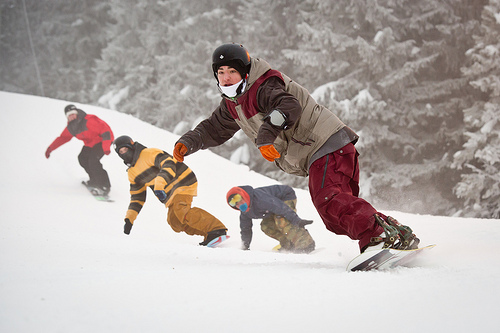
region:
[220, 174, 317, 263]
Man wearing a blue coat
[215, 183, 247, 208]
Goggle on the man's face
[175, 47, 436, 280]
Man wearing maroon pants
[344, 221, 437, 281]
Snowboard on the man's feet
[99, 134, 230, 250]
Man wearing a yellow and black jacket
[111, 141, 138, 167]
Mask covering the man's face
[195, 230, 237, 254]
Snowboard under the man's feet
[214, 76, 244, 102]
Scarf around man's face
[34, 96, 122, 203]
Man wearing a red jacket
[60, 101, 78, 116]
Hat on the man's head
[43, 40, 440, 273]
Four people on snowboards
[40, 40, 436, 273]
Four people snowboarding on a hill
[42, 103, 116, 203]
Snowboarder wearing a red winter coat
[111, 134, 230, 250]
Snowboarder wearing a winter face mask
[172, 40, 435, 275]
Man tilting sideways on a snowboard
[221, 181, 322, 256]
Person touching the snow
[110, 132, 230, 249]
Person wearing a yellow sweater with black stripes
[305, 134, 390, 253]
Burgundy colored snow pants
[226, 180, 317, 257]
Snowboarder with yellow goggles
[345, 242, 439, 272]
White and black snowboard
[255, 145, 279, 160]
an orange snow glove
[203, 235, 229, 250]
white snow board with red design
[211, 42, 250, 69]
a black safety helmet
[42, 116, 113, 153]
a red snow jacket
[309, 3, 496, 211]
snow covered trees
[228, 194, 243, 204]
reflective goggles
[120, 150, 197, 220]
yellow jacket with black stripes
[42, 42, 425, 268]
four snow boarders on the slope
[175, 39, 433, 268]
the man is snow boarding down the hill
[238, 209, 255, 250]
man's arm is on touching the snow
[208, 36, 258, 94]
boy has black cap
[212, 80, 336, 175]
red and grey coat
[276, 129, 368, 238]
boy has red pants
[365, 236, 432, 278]
boy has black shoes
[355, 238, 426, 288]
black and white snowboard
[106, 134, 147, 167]
boy has brown hood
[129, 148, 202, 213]
black and white coat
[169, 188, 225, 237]
boy has orange pants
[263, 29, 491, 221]
white snow on trees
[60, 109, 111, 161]
boy has red coat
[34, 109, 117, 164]
A man wearing a red jacket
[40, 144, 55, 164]
A man wearing red gloves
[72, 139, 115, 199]
A man wearing black pants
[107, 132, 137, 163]
A man wearing a black winter cap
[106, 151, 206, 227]
A man wearing a yellow and black jacket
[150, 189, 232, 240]
A man wearing yellow pants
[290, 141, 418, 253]
A man wearing maroon pants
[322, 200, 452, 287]
A man skiing on a snow board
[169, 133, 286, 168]
A man wearing yellow gloves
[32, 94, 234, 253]
Two people snow boarding down a hill